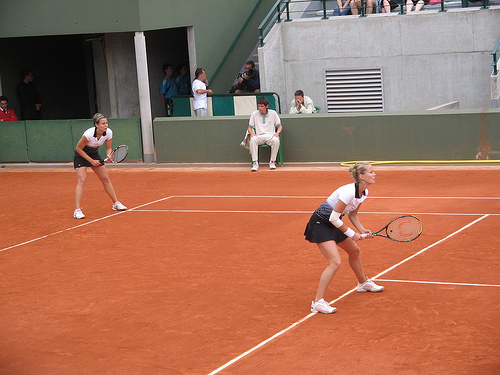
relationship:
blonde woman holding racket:
[298, 154, 407, 319] [361, 215, 423, 243]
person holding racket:
[73, 113, 127, 219] [99, 145, 128, 164]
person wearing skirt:
[73, 113, 127, 219] [74, 143, 106, 168]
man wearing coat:
[0, 96, 18, 122] [0, 109, 20, 123]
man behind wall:
[0, 96, 18, 122] [2, 114, 145, 164]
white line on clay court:
[372, 274, 499, 293] [2, 163, 499, 374]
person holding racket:
[73, 113, 127, 219] [365, 213, 430, 257]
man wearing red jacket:
[2, 97, 15, 122] [0, 97, 12, 124]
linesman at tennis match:
[240, 99, 287, 163] [13, 111, 452, 322]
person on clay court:
[303, 162, 384, 314] [2, 163, 494, 370]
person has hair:
[303, 162, 384, 314] [343, 152, 369, 176]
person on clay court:
[303, 162, 384, 314] [2, 163, 499, 374]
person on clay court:
[73, 113, 127, 219] [2, 163, 499, 374]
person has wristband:
[303, 162, 384, 314] [340, 225, 357, 241]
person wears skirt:
[73, 113, 127, 219] [71, 144, 106, 168]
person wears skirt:
[303, 162, 384, 314] [303, 206, 349, 244]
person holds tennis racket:
[303, 162, 384, 314] [356, 212, 426, 246]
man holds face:
[286, 89, 318, 118] [363, 163, 377, 188]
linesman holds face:
[248, 96, 283, 172] [96, 115, 111, 135]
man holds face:
[229, 60, 265, 93] [293, 95, 303, 105]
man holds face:
[189, 68, 211, 115] [255, 102, 267, 116]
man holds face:
[160, 63, 178, 116] [243, 64, 253, 73]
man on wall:
[158, 62, 178, 114] [91, 25, 189, 160]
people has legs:
[324, 3, 492, 16] [332, 0, 425, 15]